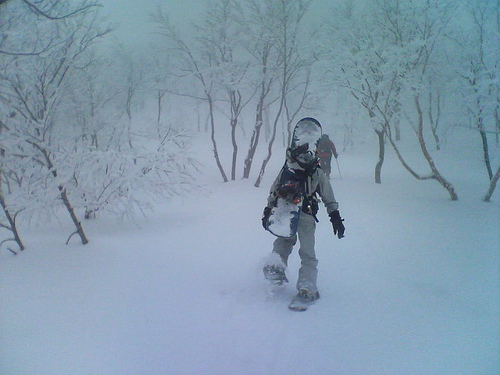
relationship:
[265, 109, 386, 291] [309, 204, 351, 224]
man in gloves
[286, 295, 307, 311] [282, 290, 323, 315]
snow on snowboard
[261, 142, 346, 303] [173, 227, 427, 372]
man on snow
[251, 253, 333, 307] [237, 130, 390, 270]
shoes on person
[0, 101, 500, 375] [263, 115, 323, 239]
snow covers snowboard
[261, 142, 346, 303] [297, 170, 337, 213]
man has coat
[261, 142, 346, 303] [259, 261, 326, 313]
man wears shoes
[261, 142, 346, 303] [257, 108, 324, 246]
man holds snow board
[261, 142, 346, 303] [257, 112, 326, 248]
man carry snowboard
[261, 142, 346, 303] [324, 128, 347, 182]
man carry ski poles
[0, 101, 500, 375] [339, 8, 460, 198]
snow on tree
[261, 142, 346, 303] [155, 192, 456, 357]
man on snow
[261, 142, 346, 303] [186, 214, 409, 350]
man on snow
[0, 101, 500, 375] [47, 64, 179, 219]
snow covering branches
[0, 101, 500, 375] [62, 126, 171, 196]
snow covering branches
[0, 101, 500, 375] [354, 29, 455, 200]
snow covering branches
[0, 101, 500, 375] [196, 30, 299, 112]
snow covering branches